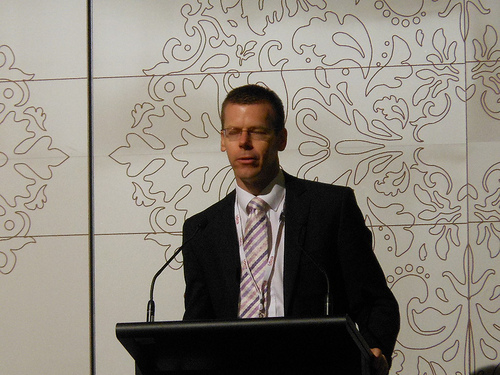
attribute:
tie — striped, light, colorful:
[239, 198, 270, 316]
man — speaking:
[182, 83, 400, 374]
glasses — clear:
[221, 124, 277, 138]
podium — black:
[115, 312, 389, 374]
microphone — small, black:
[147, 216, 212, 319]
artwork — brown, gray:
[108, 1, 499, 374]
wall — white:
[0, 0, 498, 375]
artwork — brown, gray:
[0, 45, 70, 276]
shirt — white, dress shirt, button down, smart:
[235, 172, 285, 318]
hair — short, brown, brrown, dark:
[221, 85, 284, 130]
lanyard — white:
[234, 191, 285, 316]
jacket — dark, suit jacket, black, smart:
[182, 169, 400, 360]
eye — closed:
[251, 127, 266, 136]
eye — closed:
[227, 131, 240, 138]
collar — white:
[231, 167, 286, 211]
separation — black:
[86, 1, 96, 374]